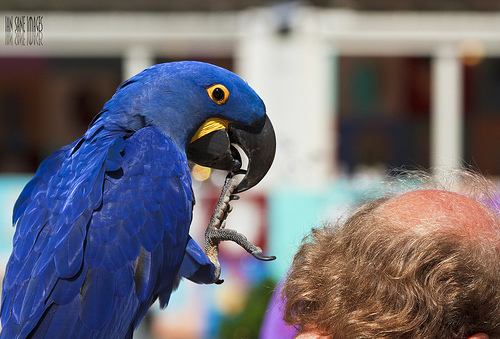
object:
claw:
[201, 167, 277, 286]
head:
[124, 59, 280, 198]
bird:
[0, 60, 275, 339]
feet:
[207, 165, 264, 276]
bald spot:
[355, 188, 497, 294]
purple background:
[260, 279, 295, 336]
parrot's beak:
[185, 112, 275, 193]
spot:
[376, 183, 498, 254]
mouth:
[180, 117, 281, 192]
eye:
[204, 79, 229, 100]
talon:
[252, 252, 278, 263]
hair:
[288, 202, 499, 337]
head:
[271, 167, 500, 338]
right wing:
[72, 131, 196, 337]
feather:
[58, 183, 148, 333]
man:
[282, 166, 498, 339]